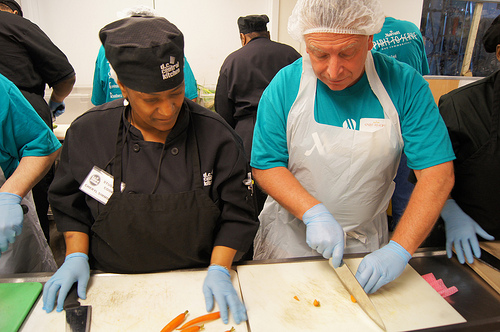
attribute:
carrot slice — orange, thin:
[161, 306, 188, 330]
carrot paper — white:
[237, 256, 465, 330]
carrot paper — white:
[21, 269, 249, 328]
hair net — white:
[286, 1, 384, 36]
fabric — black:
[216, 203, 255, 241]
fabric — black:
[53, 165, 83, 222]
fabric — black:
[458, 84, 491, 136]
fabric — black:
[405, 82, 432, 144]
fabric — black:
[196, 115, 228, 161]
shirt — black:
[201, 61, 325, 202]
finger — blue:
[217, 290, 229, 327]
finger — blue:
[228, 293, 246, 323]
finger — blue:
[60, 280, 73, 312]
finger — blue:
[46, 280, 59, 309]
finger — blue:
[443, 238, 453, 259]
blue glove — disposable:
[34, 240, 97, 315]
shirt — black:
[33, 102, 265, 262]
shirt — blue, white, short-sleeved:
[251, 54, 465, 172]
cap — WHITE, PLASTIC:
[281, 1, 386, 45]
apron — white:
[293, 63, 399, 273]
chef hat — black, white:
[102, 14, 191, 86]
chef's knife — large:
[322, 248, 385, 330]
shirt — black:
[46, 84, 271, 242]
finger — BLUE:
[200, 286, 216, 311]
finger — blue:
[467, 236, 482, 262]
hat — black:
[99, 25, 191, 82]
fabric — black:
[126, 145, 164, 190]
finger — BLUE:
[55, 282, 72, 311]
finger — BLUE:
[46, 280, 56, 310]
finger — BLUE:
[208, 277, 213, 307]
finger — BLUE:
[216, 291, 229, 323]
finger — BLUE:
[330, 239, 349, 267]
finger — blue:
[452, 239, 466, 263]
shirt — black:
[46, 104, 260, 278]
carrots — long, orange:
[162, 307, 220, 330]